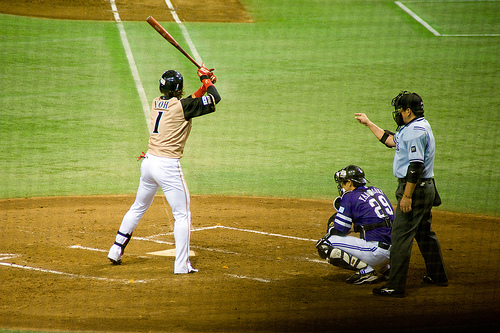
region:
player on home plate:
[118, 51, 242, 282]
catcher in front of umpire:
[286, 147, 399, 276]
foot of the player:
[169, 253, 208, 277]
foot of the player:
[100, 248, 135, 270]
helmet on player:
[151, 68, 193, 95]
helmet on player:
[340, 165, 365, 174]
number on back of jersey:
[363, 197, 398, 222]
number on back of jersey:
[151, 111, 168, 140]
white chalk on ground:
[266, 223, 281, 243]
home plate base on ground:
[146, 245, 197, 258]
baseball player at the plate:
[111, 15, 228, 287]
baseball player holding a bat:
[117, 7, 222, 259]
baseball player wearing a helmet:
[150, 58, 188, 112]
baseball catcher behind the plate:
[316, 143, 383, 305]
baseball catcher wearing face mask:
[328, 156, 368, 200]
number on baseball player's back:
[365, 186, 395, 228]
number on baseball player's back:
[149, 103, 169, 168]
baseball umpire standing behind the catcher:
[363, 89, 460, 285]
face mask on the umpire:
[380, 83, 425, 138]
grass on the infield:
[32, 97, 102, 191]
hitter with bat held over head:
[103, 12, 219, 274]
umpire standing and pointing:
[351, 86, 446, 291]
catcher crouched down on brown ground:
[310, 160, 395, 287]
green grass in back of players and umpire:
[0, 5, 492, 220]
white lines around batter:
[0, 206, 315, 291]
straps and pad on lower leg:
[102, 225, 132, 265]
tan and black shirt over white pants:
[105, 85, 217, 275]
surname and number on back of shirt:
[142, 95, 188, 156]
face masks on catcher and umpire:
[331, 57, 423, 197]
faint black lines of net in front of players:
[26, 5, 486, 321]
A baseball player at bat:
[107, 46, 228, 283]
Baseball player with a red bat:
[97, 7, 221, 291]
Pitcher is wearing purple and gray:
[310, 139, 394, 304]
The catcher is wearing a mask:
[316, 149, 376, 196]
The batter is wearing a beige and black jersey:
[131, 67, 224, 153]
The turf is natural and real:
[231, 154, 277, 231]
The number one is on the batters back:
[141, 102, 193, 152]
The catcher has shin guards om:
[297, 213, 384, 295]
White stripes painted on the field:
[99, 4, 144, 72]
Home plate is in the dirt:
[147, 242, 204, 261]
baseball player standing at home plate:
[61, 11, 246, 296]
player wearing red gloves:
[84, 10, 227, 308]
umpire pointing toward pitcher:
[347, 72, 454, 299]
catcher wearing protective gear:
[310, 161, 402, 287]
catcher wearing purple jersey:
[296, 159, 412, 287]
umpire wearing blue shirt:
[332, 92, 482, 309]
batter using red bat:
[58, 7, 250, 287]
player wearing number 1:
[91, 7, 226, 283]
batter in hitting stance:
[84, 12, 256, 297]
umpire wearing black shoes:
[349, 79, 460, 310]